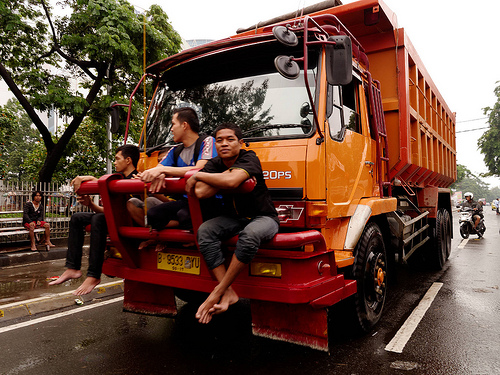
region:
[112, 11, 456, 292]
a large orange truck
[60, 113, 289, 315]
group of young men ride the front of truck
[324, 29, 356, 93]
side mirrors of truck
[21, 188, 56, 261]
seated person watches truck drive by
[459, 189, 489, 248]
person of motorbike trails the truck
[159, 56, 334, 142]
windshield of truck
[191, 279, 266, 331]
man is barefooted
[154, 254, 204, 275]
yellow license plate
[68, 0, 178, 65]
green leaves of a tree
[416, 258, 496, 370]
rain slicked road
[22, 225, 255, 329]
"The men are barefooted"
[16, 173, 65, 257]
"Someone is sitting on a bench"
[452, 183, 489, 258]
"A man on a moped"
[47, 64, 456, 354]
"Three men rides on the front of a truck"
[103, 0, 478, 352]
"An orange and red truck"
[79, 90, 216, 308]
"Two men looking to their right"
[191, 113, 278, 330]
"Man looking ahead at the camera"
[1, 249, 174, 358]
"The road and sidewalk is wet"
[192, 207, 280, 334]
"Sitting with his feet crossed"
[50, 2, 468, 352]
"The truck is big and bright colored"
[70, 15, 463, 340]
A large orange dump truck.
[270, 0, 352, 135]
A set of mirrors.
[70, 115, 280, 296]
Three boys sitting on the front of the truck.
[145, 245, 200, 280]
License plate.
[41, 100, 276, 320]
The boys are all barefoot.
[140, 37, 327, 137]
The windshield.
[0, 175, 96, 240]
A metal fence.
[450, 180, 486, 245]
A man on a scooter.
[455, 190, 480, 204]
The man has a white helmet on his head.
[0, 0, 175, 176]
A large tree behind the fence.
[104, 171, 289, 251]
the metal bar is red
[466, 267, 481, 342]
the road is wet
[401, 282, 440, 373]
the stripe is white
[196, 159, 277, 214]
the top is black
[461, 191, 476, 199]
the helmet is white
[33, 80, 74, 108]
the tree is green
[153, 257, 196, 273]
the number plate is yellow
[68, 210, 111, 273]
the pants are black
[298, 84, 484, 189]
the truck is orange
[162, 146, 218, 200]
the top is blue and grey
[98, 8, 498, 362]
Orange and red dump truck on road.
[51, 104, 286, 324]
Three men sitting in front of dump truck.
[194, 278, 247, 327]
A man's crossed bear feet.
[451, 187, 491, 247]
Man on motorbike behind dump truck.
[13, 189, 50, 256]
Man sitting on bench on sidewalk.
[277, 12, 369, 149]
Side view mirrors on dump truck.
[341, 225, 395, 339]
Front left tire of dump truck.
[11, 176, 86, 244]
Metal fence behind bench on sidewalk.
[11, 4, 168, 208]
Tree growing behind fence on sidewalk.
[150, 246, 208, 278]
Yellow and black tag on front bumper of dump truck.